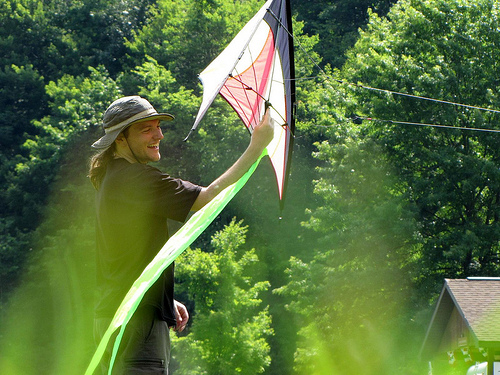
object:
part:
[210, 217, 253, 253]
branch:
[207, 213, 250, 270]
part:
[260, 95, 293, 201]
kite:
[183, 0, 296, 215]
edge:
[423, 280, 448, 346]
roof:
[420, 275, 499, 348]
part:
[311, 75, 432, 100]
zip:
[312, 75, 500, 113]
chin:
[146, 148, 162, 161]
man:
[88, 93, 274, 375]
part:
[461, 304, 500, 340]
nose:
[153, 126, 163, 141]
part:
[252, 128, 275, 142]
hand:
[248, 109, 275, 147]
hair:
[87, 140, 120, 187]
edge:
[197, 0, 268, 78]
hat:
[90, 96, 174, 151]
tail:
[89, 150, 268, 373]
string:
[297, 107, 499, 134]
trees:
[347, 57, 500, 287]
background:
[0, 2, 498, 374]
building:
[419, 275, 500, 374]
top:
[95, 61, 202, 91]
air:
[2, 2, 498, 374]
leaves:
[397, 119, 429, 164]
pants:
[95, 316, 175, 371]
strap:
[124, 128, 142, 164]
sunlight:
[43, 60, 124, 100]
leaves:
[44, 64, 78, 107]